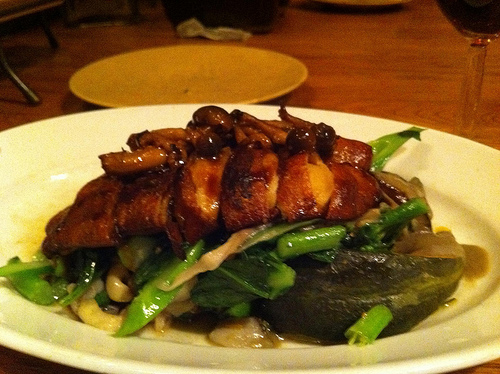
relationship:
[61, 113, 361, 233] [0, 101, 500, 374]
meat on plate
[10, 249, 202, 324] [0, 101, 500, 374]
vegetables on plate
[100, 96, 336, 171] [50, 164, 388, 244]
mushrooms on meat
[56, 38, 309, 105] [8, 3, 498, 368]
plate on table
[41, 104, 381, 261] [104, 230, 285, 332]
meat on vegetables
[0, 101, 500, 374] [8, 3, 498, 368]
plate on table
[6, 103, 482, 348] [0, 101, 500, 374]
food in plate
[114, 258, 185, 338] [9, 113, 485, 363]
bean on plate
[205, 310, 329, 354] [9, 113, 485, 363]
sauce on plate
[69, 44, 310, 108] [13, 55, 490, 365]
plate on table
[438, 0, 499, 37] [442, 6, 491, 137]
wine in glass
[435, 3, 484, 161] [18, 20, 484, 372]
glass on table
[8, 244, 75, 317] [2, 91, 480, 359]
leaf on plate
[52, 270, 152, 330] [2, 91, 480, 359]
onions on plate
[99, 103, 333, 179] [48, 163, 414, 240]
mushrooms on pork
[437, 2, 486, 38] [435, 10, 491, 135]
wine in glass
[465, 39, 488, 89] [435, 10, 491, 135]
stem of glass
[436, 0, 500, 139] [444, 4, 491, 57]
glass of wine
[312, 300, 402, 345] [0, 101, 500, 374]
bean on plate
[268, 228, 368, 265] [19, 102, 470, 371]
bean on plate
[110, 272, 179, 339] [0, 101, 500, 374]
bean on plate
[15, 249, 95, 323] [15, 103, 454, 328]
bean on plate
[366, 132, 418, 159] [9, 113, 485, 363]
bean on plate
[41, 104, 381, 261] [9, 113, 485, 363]
meat on plate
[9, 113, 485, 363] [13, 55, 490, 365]
plate on table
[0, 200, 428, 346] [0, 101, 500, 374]
vegetables on plate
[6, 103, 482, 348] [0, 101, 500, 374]
food on plate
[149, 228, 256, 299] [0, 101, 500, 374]
shallots on plate